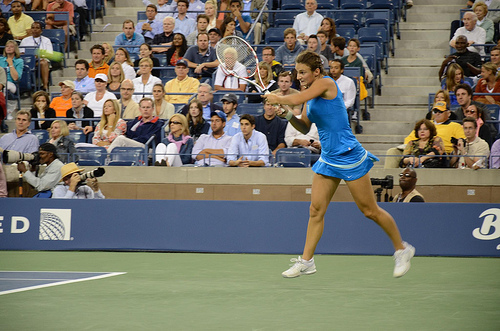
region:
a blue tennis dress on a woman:
[302, 74, 377, 181]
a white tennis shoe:
[284, 252, 314, 281]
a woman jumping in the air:
[262, 49, 415, 279]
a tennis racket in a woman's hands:
[213, 34, 278, 99]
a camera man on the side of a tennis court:
[368, 160, 425, 208]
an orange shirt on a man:
[45, 95, 77, 118]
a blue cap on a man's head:
[209, 107, 229, 118]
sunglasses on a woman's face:
[166, 118, 184, 127]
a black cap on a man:
[38, 141, 60, 154]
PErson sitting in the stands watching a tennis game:
[232, 111, 272, 170]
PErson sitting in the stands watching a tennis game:
[199, 101, 229, 166]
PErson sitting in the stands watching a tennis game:
[153, 105, 192, 168]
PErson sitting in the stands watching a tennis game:
[450, 109, 489, 180]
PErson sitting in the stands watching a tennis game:
[445, 9, 482, 55]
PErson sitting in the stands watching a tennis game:
[449, 27, 482, 83]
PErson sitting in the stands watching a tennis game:
[295, 3, 320, 46]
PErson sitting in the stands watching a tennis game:
[161, 51, 203, 118]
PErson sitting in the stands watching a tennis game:
[128, 47, 158, 118]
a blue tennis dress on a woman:
[301, 76, 381, 182]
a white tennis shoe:
[281, 258, 319, 279]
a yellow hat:
[53, 159, 83, 183]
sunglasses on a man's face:
[394, 171, 416, 179]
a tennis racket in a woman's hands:
[209, 34, 278, 100]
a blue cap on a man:
[209, 105, 232, 123]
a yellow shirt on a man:
[400, 114, 469, 153]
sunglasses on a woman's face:
[168, 118, 186, 126]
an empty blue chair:
[274, 143, 314, 171]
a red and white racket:
[214, 31, 278, 100]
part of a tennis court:
[3, 242, 494, 328]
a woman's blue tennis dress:
[292, 73, 380, 179]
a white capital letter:
[10, 213, 32, 235]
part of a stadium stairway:
[355, 0, 452, 169]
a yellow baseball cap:
[430, 98, 449, 110]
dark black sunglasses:
[166, 115, 183, 125]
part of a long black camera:
[367, 170, 396, 190]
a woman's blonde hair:
[165, 113, 187, 138]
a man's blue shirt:
[2, 127, 36, 152]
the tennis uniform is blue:
[300, 81, 377, 192]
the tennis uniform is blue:
[267, 46, 384, 223]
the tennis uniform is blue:
[268, 46, 405, 233]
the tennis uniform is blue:
[273, 69, 393, 214]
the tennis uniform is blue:
[280, 51, 386, 213]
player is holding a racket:
[195, 25, 377, 247]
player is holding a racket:
[189, 16, 367, 184]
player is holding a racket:
[182, 14, 358, 166]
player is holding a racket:
[198, 12, 355, 177]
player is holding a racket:
[185, 26, 369, 178]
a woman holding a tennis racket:
[214, 26, 281, 120]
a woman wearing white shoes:
[280, 252, 318, 281]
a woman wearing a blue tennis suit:
[299, 81, 383, 191]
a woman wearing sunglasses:
[166, 111, 186, 128]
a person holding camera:
[57, 161, 104, 190]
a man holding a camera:
[365, 165, 422, 200]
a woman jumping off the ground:
[256, 37, 427, 321]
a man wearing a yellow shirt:
[430, 116, 467, 146]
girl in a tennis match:
[261, 45, 418, 287]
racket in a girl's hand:
[209, 29, 288, 119]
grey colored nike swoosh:
[296, 266, 313, 274]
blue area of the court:
[1, 263, 125, 307]